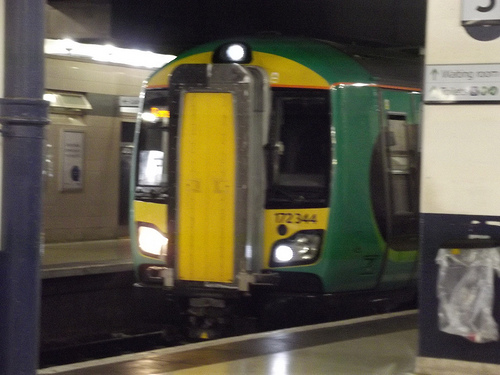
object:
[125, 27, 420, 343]
train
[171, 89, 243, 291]
door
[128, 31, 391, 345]
front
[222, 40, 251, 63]
light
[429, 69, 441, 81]
arrow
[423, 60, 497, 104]
direction map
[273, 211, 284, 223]
number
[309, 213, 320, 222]
number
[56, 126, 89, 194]
poster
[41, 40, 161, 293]
wall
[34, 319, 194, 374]
train tracks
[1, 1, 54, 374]
pole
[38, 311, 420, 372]
platform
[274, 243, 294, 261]
headlight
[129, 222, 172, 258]
headlight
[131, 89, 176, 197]
windshield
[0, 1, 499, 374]
train station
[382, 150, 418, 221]
window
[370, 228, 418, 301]
ladder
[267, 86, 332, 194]
windshield